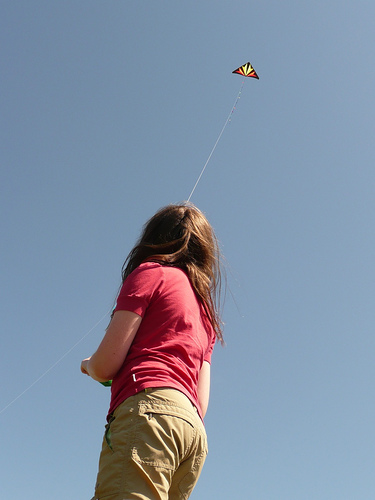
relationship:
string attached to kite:
[186, 81, 245, 205] [223, 49, 274, 79]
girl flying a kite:
[80, 202, 226, 500] [199, 50, 286, 127]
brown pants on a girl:
[94, 380, 216, 497] [80, 202, 226, 500]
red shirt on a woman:
[106, 262, 213, 423] [70, 198, 230, 498]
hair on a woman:
[121, 204, 226, 349] [80, 201, 225, 498]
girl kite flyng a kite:
[79, 60, 260, 498] [217, 44, 268, 99]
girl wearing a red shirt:
[80, 202, 226, 500] [104, 262, 214, 420]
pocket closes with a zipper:
[131, 401, 194, 470] [135, 408, 160, 432]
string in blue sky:
[182, 80, 240, 210] [0, 0, 375, 499]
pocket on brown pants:
[104, 409, 121, 464] [93, 388, 208, 500]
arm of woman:
[189, 344, 215, 419] [70, 198, 230, 498]